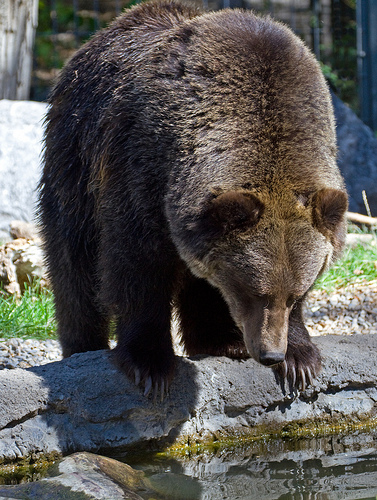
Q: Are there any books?
A: No, there are no books.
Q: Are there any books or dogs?
A: No, there are no books or dogs.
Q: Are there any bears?
A: Yes, there is a bear.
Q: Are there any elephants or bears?
A: Yes, there is a bear.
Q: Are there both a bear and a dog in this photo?
A: No, there is a bear but no dogs.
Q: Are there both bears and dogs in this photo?
A: No, there is a bear but no dogs.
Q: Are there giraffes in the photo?
A: No, there are no giraffes.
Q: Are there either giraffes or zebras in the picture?
A: No, there are no giraffes or zebras.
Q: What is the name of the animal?
A: The animal is a bear.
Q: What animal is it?
A: The animal is a bear.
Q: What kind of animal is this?
A: This is a bear.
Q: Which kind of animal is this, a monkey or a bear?
A: This is a bear.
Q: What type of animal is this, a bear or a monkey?
A: This is a bear.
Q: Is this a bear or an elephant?
A: This is a bear.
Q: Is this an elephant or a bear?
A: This is a bear.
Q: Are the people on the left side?
A: Yes, the people are on the left of the image.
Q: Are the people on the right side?
A: No, the people are on the left of the image.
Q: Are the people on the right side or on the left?
A: The people are on the left of the image.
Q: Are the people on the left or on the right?
A: The people are on the left of the image.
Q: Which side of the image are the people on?
A: The people are on the left of the image.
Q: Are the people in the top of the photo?
A: Yes, the people are in the top of the image.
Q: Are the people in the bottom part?
A: No, the people are in the top of the image.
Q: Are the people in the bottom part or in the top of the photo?
A: The people are in the top of the image.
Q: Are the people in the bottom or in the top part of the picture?
A: The people are in the top of the image.